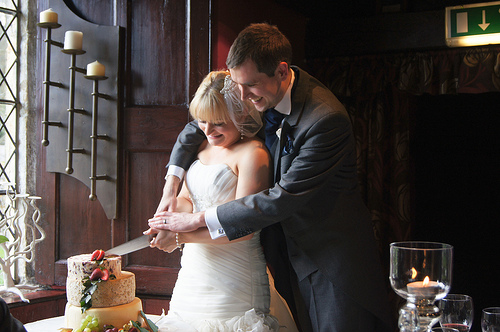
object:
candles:
[36, 8, 59, 28]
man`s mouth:
[248, 95, 264, 107]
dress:
[152, 159, 280, 332]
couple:
[140, 22, 401, 332]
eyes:
[243, 81, 258, 91]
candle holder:
[413, 295, 441, 332]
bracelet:
[169, 228, 186, 252]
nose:
[237, 89, 252, 101]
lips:
[250, 96, 262, 105]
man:
[150, 23, 391, 331]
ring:
[160, 216, 170, 226]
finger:
[156, 224, 170, 231]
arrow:
[474, 7, 490, 32]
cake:
[53, 248, 158, 331]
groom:
[148, 24, 396, 331]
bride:
[142, 69, 285, 331]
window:
[0, 0, 34, 285]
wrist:
[170, 232, 190, 247]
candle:
[86, 60, 103, 77]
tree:
[0, 185, 43, 303]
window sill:
[0, 279, 67, 324]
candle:
[406, 276, 441, 295]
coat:
[163, 66, 398, 331]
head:
[225, 24, 295, 112]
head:
[190, 68, 254, 147]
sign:
[442, 1, 499, 47]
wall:
[35, 0, 499, 332]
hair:
[188, 65, 264, 129]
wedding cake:
[63, 246, 143, 331]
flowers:
[90, 247, 104, 262]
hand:
[146, 210, 203, 232]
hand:
[153, 188, 178, 216]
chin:
[249, 102, 269, 112]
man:
[154, 21, 396, 330]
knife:
[103, 233, 151, 258]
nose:
[200, 120, 217, 135]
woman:
[143, 70, 278, 332]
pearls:
[170, 231, 186, 250]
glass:
[388, 241, 454, 331]